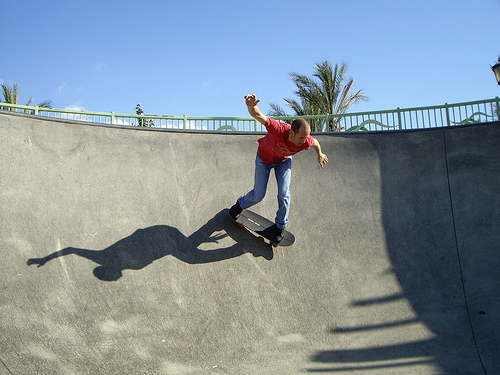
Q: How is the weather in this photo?
A: Clear and sunny.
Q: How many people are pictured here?
A: One.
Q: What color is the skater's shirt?
A: Red.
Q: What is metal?
A: Rail.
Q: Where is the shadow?
A: On the wall.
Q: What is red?
A: Shirt.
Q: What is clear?
A: Sky.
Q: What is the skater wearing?
A: Blue jeans.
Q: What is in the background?
A: Trees.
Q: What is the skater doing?
A: Skating.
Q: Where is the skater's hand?
A: In the air.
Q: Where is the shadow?
A: Concrete.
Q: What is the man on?
A: Skateboard.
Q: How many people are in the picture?
A: 1.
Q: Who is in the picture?
A: A man.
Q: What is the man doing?
A: Skateboarding.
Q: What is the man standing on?
A: A skateboard.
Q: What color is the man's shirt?
A: Red.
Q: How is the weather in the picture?
A: Sunny.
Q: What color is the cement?
A: Gray.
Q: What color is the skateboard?
A: Black.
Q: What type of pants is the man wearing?
A: Jeans.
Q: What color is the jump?
A: Grey.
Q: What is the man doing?
A: Skateboarding.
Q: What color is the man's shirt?
A: Red.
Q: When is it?
A: Daytime.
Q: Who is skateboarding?
A: The man.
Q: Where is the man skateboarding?
A: The skate park.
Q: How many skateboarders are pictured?
A: One.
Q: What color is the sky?
A: Blue.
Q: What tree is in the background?
A: A palm tree.